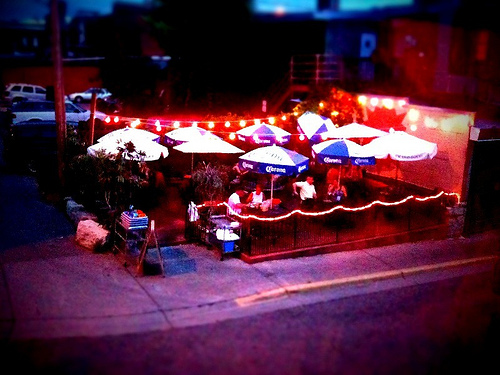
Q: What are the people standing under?
A: Umbrellas.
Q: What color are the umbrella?
A: Red, white, blue.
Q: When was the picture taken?
A: At night.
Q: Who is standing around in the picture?
A: People.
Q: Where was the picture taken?
A: Cafe.